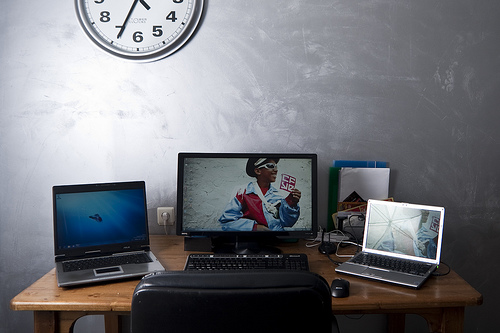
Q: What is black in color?
A: Computer chair.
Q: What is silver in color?
A: Clock frame.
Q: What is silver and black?
A: Laptop.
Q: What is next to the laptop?
A: A monitor.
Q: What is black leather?
A: The chair.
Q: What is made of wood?
A: The desk.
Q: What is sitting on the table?
A: Computers.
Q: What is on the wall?
A: A clock.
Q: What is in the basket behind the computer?
A: The papers.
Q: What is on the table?
A: The computer screen.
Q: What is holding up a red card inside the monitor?
A: The man.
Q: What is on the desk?
A: Laptop computer.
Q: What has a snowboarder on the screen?
A: The small laptop.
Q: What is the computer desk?
A: Brown.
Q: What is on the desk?
A: Three computers.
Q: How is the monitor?
A: On.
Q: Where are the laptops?
A: On table.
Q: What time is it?
A: 4:34.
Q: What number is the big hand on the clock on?
A: The seven.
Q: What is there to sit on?
A: A black chair.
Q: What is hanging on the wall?
A: A silver clock.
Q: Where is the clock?
A: Hanging on the wall.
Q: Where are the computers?
A: On the desk.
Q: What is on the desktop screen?
A: A person in sunglasses.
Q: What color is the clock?
A: Silver.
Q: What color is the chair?
A: Black.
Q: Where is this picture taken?
A: In a room at a desk.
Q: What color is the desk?
A: Brown.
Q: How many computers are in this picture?
A: Three.